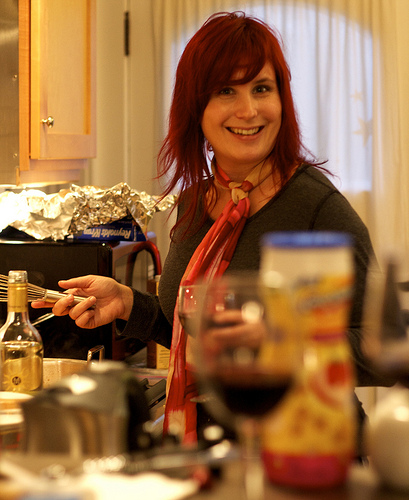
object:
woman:
[31, 10, 371, 425]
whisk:
[1, 270, 47, 390]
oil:
[0, 368, 42, 389]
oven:
[3, 194, 150, 357]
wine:
[208, 365, 296, 417]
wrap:
[69, 180, 176, 229]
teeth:
[243, 130, 248, 135]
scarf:
[200, 154, 286, 220]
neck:
[203, 160, 288, 194]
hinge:
[122, 9, 131, 61]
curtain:
[296, 0, 409, 246]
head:
[149, 15, 314, 189]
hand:
[30, 272, 130, 332]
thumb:
[56, 272, 89, 292]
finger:
[51, 294, 74, 317]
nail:
[66, 293, 72, 301]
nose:
[236, 100, 259, 121]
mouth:
[221, 124, 265, 141]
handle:
[40, 115, 55, 129]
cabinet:
[24, 0, 99, 162]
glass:
[174, 271, 218, 326]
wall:
[39, 28, 168, 196]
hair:
[161, 5, 306, 168]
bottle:
[0, 266, 45, 395]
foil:
[27, 221, 46, 232]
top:
[153, 171, 403, 413]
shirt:
[125, 176, 392, 443]